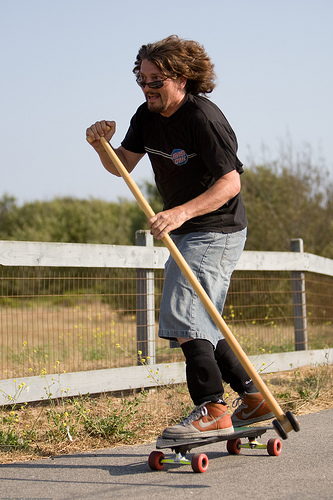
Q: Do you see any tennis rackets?
A: No, there are no tennis rackets.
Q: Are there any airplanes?
A: No, there are no airplanes.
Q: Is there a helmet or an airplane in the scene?
A: No, there are no airplanes or helmets.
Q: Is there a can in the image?
A: No, there are no cans.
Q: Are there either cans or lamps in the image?
A: No, there are no cans or lamps.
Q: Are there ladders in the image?
A: No, there are no ladders.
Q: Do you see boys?
A: No, there are no boys.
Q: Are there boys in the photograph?
A: No, there are no boys.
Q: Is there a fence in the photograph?
A: Yes, there is a fence.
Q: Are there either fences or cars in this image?
A: Yes, there is a fence.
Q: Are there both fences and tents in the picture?
A: No, there is a fence but no tents.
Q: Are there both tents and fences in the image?
A: No, there is a fence but no tents.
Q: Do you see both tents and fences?
A: No, there is a fence but no tents.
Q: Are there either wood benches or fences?
A: Yes, there is a wood fence.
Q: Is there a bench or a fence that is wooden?
A: Yes, the fence is wooden.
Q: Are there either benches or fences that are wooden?
A: Yes, the fence is wooden.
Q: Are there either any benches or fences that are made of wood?
A: Yes, the fence is made of wood.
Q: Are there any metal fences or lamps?
A: Yes, there is a metal fence.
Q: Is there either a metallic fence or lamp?
A: Yes, there is a metal fence.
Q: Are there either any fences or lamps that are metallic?
A: Yes, the fence is metallic.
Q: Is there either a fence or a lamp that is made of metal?
A: Yes, the fence is made of metal.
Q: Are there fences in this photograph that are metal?
A: Yes, there is a metal fence.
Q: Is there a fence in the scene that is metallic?
A: Yes, there is a fence that is metallic.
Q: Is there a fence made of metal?
A: Yes, there is a fence that is made of metal.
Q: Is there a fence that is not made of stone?
A: Yes, there is a fence that is made of metal.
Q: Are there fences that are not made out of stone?
A: Yes, there is a fence that is made of metal.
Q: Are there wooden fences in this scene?
A: Yes, there is a wood fence.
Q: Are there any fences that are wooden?
A: Yes, there is a fence that is wooden.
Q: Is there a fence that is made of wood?
A: Yes, there is a fence that is made of wood.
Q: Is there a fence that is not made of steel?
A: Yes, there is a fence that is made of wood.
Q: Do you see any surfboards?
A: No, there are no surfboards.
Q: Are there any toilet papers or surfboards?
A: No, there are no surfboards or toilet papers.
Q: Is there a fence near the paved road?
A: Yes, there is a fence near the road.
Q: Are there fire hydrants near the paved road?
A: No, there is a fence near the road.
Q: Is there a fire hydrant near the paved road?
A: No, there is a fence near the road.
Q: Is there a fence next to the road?
A: Yes, there is a fence next to the road.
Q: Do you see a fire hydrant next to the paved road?
A: No, there is a fence next to the road.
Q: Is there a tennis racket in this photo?
A: No, there are no rackets.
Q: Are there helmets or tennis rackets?
A: No, there are no tennis rackets or helmets.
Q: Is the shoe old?
A: Yes, the shoe is old.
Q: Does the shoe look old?
A: Yes, the shoe is old.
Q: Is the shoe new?
A: No, the shoe is old.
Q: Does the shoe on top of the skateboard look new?
A: No, the shoe is old.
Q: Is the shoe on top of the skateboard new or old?
A: The shoe is old.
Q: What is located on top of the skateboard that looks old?
A: The shoe is on top of the skateboard.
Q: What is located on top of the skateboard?
A: The shoe is on top of the skateboard.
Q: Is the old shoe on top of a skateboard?
A: Yes, the shoe is on top of a skateboard.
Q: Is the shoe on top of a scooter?
A: No, the shoe is on top of a skateboard.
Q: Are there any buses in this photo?
A: No, there are no buses.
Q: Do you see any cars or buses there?
A: No, there are no buses or cars.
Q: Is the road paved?
A: Yes, the road is paved.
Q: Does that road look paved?
A: Yes, the road is paved.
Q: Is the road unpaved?
A: No, the road is paved.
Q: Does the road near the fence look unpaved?
A: No, the road is paved.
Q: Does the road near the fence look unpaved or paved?
A: The road is paved.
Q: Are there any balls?
A: No, there are no balls.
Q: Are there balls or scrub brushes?
A: No, there are no balls or scrub brushes.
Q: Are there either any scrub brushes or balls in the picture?
A: No, there are no balls or scrub brushes.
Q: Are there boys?
A: No, there are no boys.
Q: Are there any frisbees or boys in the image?
A: No, there are no boys or frisbees.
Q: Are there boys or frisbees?
A: No, there are no boys or frisbees.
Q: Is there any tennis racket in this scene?
A: No, there are no rackets.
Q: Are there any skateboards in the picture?
A: Yes, there is a skateboard.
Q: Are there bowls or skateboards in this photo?
A: Yes, there is a skateboard.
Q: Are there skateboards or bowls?
A: Yes, there is a skateboard.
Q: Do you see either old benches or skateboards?
A: Yes, there is an old skateboard.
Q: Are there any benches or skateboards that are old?
A: Yes, the skateboard is old.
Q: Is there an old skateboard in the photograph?
A: Yes, there is an old skateboard.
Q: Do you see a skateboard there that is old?
A: Yes, there is a skateboard that is old.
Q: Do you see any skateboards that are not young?
A: Yes, there is a old skateboard.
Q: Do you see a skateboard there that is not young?
A: Yes, there is a old skateboard.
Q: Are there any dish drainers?
A: No, there are no dish drainers.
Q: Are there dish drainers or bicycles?
A: No, there are no dish drainers or bicycles.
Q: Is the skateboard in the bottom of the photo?
A: Yes, the skateboard is in the bottom of the image.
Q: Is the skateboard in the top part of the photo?
A: No, the skateboard is in the bottom of the image.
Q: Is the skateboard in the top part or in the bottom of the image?
A: The skateboard is in the bottom of the image.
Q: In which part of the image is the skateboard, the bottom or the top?
A: The skateboard is in the bottom of the image.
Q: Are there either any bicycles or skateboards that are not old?
A: No, there is a skateboard but it is old.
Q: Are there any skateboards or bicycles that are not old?
A: No, there is a skateboard but it is old.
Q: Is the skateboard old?
A: Yes, the skateboard is old.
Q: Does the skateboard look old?
A: Yes, the skateboard is old.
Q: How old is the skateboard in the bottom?
A: The skateboard is old.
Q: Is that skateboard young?
A: No, the skateboard is old.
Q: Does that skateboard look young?
A: No, the skateboard is old.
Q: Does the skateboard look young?
A: No, the skateboard is old.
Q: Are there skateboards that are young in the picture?
A: No, there is a skateboard but it is old.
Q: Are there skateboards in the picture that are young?
A: No, there is a skateboard but it is old.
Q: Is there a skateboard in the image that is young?
A: No, there is a skateboard but it is old.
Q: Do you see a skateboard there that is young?
A: No, there is a skateboard but it is old.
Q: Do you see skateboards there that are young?
A: No, there is a skateboard but it is old.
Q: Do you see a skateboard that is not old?
A: No, there is a skateboard but it is old.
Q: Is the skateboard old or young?
A: The skateboard is old.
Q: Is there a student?
A: No, there are no students.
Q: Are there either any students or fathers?
A: No, there are no students or fathers.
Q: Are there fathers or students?
A: No, there are no students or fathers.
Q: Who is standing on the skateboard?
A: The man is standing on the skateboard.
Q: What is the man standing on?
A: The man is standing on the skateboard.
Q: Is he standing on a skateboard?
A: Yes, the man is standing on a skateboard.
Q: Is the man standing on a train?
A: No, the man is standing on a skateboard.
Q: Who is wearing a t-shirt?
A: The man is wearing a t-shirt.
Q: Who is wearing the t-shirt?
A: The man is wearing a t-shirt.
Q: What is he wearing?
A: The man is wearing a tee shirt.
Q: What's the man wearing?
A: The man is wearing a tee shirt.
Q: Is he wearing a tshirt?
A: Yes, the man is wearing a tshirt.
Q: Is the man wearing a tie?
A: No, the man is wearing a tshirt.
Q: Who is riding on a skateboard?
A: The man is riding on a skateboard.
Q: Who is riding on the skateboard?
A: The man is riding on a skateboard.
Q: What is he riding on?
A: The man is riding on a skateboard.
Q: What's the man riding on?
A: The man is riding on a skateboard.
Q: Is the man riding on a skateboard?
A: Yes, the man is riding on a skateboard.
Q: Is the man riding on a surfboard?
A: No, the man is riding on a skateboard.